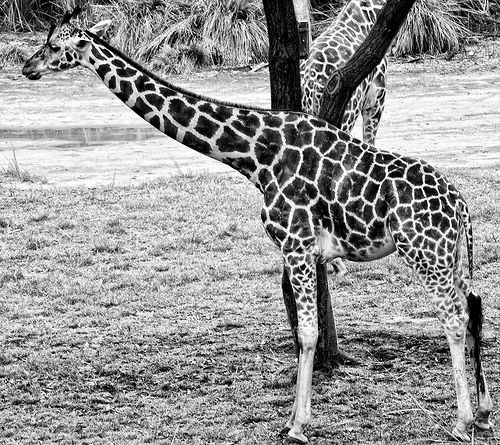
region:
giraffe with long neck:
[22, 3, 494, 443]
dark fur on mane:
[86, 28, 290, 115]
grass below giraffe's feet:
[6, 169, 488, 441]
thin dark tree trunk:
[260, 0, 415, 370]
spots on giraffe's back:
[262, 115, 463, 254]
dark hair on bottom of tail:
[457, 205, 487, 398]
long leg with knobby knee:
[282, 258, 319, 443]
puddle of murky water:
[2, 116, 164, 153]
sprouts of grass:
[81, 5, 470, 65]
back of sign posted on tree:
[294, 18, 311, 60]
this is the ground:
[98, 242, 148, 292]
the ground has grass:
[88, 242, 189, 320]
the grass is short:
[59, 238, 168, 305]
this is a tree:
[259, 2, 399, 110]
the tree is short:
[268, 7, 311, 92]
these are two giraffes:
[20, 15, 480, 425]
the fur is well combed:
[295, 163, 325, 188]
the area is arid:
[78, 143, 108, 163]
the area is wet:
[88, 130, 120, 143]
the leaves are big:
[182, 21, 231, 61]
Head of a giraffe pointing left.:
[20, 7, 113, 81]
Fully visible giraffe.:
[20, 4, 491, 444]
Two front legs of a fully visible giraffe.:
[278, 245, 321, 442]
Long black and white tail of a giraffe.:
[456, 200, 484, 395]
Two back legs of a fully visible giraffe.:
[387, 220, 494, 441]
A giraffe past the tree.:
[297, 0, 388, 150]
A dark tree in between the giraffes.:
[258, 1, 412, 364]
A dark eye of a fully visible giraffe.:
[48, 41, 61, 51]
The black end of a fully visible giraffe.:
[461, 290, 484, 405]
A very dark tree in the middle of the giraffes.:
[259, 0, 418, 360]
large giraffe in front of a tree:
[29, 19, 495, 431]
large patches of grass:
[104, 320, 171, 377]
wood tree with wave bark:
[261, 10, 303, 87]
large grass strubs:
[145, 12, 214, 63]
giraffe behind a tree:
[277, 6, 397, 141]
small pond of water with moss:
[17, 119, 102, 159]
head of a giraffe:
[11, 16, 111, 91]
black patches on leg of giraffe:
[457, 290, 497, 382]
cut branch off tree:
[320, 68, 347, 98]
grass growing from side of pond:
[0, 138, 55, 190]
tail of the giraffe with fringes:
[462, 218, 499, 415]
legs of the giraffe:
[269, 267, 489, 443]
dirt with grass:
[51, 183, 228, 436]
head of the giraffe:
[25, 11, 112, 81]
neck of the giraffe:
[105, 45, 230, 150]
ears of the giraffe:
[75, 16, 113, 52]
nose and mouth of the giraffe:
[20, 55, 42, 85]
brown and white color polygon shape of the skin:
[236, 123, 403, 236]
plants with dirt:
[157, 11, 264, 89]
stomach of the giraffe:
[318, 154, 393, 257]